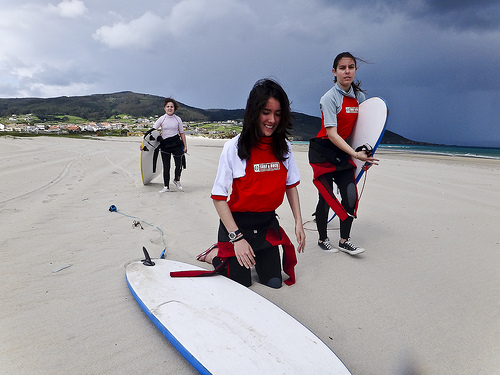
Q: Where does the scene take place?
A: At the beach.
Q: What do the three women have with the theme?
A: Surfboards.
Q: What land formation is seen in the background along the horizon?
A: Mountains.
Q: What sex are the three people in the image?
A: Female.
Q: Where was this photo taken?
A: At a beach.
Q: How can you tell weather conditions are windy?
A: The woman's hair is blowing around.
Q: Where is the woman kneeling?
A: Next to a surfboard.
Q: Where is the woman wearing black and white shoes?
A: Standing on the beach.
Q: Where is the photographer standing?
A: In front of the women.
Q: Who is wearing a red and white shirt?
A: The woman kneeling on the sand.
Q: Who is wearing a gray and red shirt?
A: The woman walking on the beach.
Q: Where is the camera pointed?
A: Toward the three women.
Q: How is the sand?
A: Brown.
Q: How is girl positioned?
A: On knees.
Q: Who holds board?
A: Girl.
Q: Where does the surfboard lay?
A: On beach.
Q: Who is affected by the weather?
A: Girl surfer on a windy day.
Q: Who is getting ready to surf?
A: Girl.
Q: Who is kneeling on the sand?
A: Girl.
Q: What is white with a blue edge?
A: Surf board.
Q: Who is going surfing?
A: Trio of girls.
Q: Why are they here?
A: To surf.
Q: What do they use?
A: Surfboards.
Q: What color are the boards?
A: White and blue.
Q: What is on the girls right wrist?
A: A watch.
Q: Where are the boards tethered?
A: On the surfers ankle.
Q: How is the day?
A: Gray and cloudy.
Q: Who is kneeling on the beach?
A: The girl with the long dark hair.